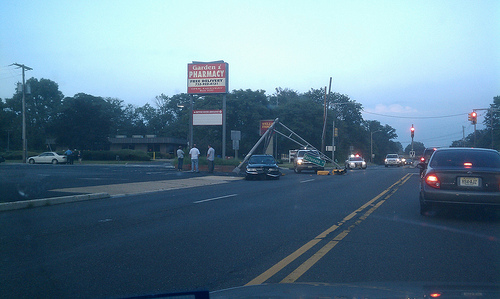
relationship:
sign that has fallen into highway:
[229, 115, 344, 176] [0, 161, 499, 298]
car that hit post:
[243, 154, 283, 181] [236, 117, 328, 166]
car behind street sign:
[292, 149, 326, 173] [230, 117, 343, 177]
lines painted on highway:
[271, 177, 409, 284] [135, 161, 497, 291]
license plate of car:
[460, 176, 482, 188] [419, 147, 499, 219]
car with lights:
[343, 153, 367, 170] [350, 153, 359, 158]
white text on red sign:
[189, 60, 224, 78] [183, 55, 230, 95]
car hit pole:
[243, 154, 283, 181] [238, 120, 275, 171]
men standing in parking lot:
[173, 141, 219, 172] [2, 161, 182, 191]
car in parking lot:
[23, 149, 73, 166] [0, 160, 240, 213]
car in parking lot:
[240, 150, 285, 178] [0, 160, 240, 213]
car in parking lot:
[415, 147, 498, 221] [0, 160, 240, 213]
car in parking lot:
[343, 148, 367, 172] [0, 160, 240, 213]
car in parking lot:
[287, 142, 334, 174] [0, 160, 240, 213]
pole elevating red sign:
[216, 97, 228, 166] [186, 62, 229, 93]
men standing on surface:
[175, 136, 217, 181] [244, 196, 420, 282]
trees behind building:
[3, 52, 160, 157] [107, 129, 187, 158]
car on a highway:
[243, 154, 283, 181] [0, 161, 499, 298]